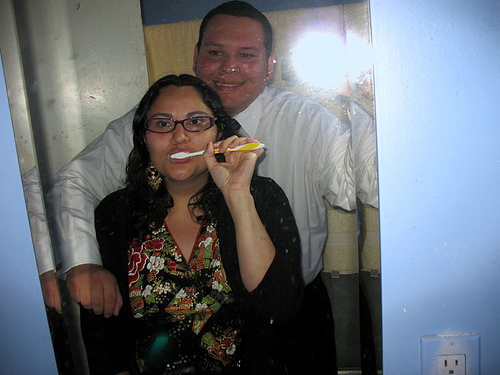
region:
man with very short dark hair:
[186, 0, 294, 125]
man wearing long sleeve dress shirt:
[38, 7, 373, 304]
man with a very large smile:
[165, 10, 300, 130]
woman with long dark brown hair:
[95, 56, 257, 246]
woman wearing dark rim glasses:
[96, 70, 268, 167]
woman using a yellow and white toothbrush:
[135, 63, 302, 184]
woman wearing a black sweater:
[52, 60, 329, 318]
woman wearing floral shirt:
[60, 70, 324, 360]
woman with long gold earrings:
[93, 66, 274, 233]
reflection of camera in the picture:
[125, 12, 368, 155]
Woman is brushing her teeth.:
[133, 141, 289, 168]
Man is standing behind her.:
[163, 2, 287, 139]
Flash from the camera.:
[286, 25, 370, 91]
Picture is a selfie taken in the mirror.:
[16, 19, 433, 371]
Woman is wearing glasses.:
[131, 102, 223, 139]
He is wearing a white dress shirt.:
[264, 113, 328, 193]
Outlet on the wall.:
[406, 322, 489, 374]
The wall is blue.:
[387, 101, 495, 268]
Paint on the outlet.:
[416, 330, 493, 357]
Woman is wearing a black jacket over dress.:
[96, 202, 318, 372]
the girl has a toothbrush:
[166, 144, 264, 167]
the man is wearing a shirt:
[44, 90, 376, 301]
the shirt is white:
[52, 77, 384, 309]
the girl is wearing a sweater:
[75, 170, 327, 373]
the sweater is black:
[81, 172, 307, 348]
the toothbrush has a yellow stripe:
[208, 136, 269, 161]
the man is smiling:
[212, 74, 259, 93]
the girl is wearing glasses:
[145, 108, 224, 133]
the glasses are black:
[139, 110, 221, 140]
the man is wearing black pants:
[239, 263, 347, 373]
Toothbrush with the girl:
[167, 148, 269, 160]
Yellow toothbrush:
[164, 148, 280, 161]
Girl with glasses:
[136, 90, 261, 178]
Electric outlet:
[406, 316, 488, 372]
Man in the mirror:
[187, 11, 347, 201]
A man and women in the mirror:
[52, 13, 329, 323]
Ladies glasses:
[146, 111, 216, 134]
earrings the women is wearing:
[139, 157, 171, 198]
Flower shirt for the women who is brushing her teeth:
[127, 235, 233, 337]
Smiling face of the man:
[215, 70, 259, 104]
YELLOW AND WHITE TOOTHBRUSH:
[170, 128, 277, 166]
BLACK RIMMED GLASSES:
[147, 111, 219, 141]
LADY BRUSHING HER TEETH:
[100, 67, 283, 277]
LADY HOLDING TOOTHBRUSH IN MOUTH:
[100, 73, 311, 300]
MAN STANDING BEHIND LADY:
[30, 7, 367, 302]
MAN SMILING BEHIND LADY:
[12, 7, 386, 259]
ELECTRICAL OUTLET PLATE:
[410, 328, 499, 373]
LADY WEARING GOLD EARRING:
[141, 160, 165, 190]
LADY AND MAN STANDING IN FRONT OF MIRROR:
[16, 2, 466, 374]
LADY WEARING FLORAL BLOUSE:
[104, 211, 238, 371]